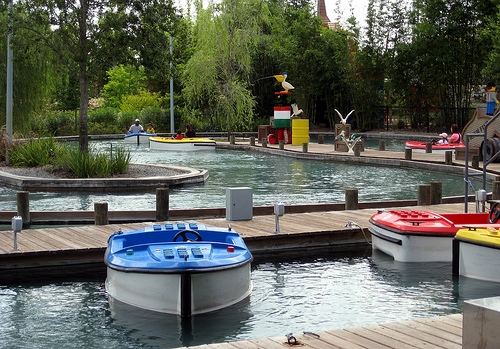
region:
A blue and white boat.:
[80, 186, 276, 326]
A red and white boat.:
[345, 190, 478, 268]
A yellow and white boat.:
[455, 205, 497, 291]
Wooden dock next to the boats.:
[155, 306, 478, 346]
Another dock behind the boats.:
[0, 185, 497, 268]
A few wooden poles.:
[11, 185, 181, 216]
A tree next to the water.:
[15, 1, 156, 171]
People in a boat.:
[115, 105, 160, 146]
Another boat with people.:
[391, 121, 471, 156]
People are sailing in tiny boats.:
[3, 5, 497, 347]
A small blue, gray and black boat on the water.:
[101, 221, 256, 318]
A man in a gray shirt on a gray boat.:
[125, 115, 145, 136]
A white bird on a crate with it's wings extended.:
[333, 106, 355, 124]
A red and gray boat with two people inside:
[400, 130, 465, 158]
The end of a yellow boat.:
[450, 220, 499, 285]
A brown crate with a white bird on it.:
[332, 121, 352, 150]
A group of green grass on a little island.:
[46, 144, 132, 176]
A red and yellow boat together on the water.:
[367, 205, 494, 285]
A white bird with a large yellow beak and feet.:
[271, 73, 296, 94]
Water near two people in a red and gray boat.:
[309, 129, 441, 146]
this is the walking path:
[48, 225, 95, 243]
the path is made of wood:
[41, 224, 92, 247]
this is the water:
[207, 152, 245, 177]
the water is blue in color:
[211, 155, 238, 173]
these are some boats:
[104, 212, 496, 319]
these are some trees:
[196, 2, 486, 65]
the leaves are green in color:
[186, 27, 241, 124]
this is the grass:
[58, 152, 118, 164]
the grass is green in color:
[56, 160, 91, 170]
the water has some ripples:
[280, 272, 337, 296]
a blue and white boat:
[96, 215, 269, 322]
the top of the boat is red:
[367, 211, 499, 231]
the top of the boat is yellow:
[454, 229, 499, 247]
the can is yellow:
[293, 114, 312, 144]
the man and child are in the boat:
[123, 117, 158, 136]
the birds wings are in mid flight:
[331, 107, 356, 124]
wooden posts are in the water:
[139, 184, 174, 217]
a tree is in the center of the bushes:
[74, 0, 91, 166]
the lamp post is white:
[163, 35, 179, 135]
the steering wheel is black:
[171, 227, 209, 246]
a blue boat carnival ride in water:
[92, 223, 299, 315]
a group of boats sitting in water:
[0, 91, 497, 344]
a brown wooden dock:
[173, 308, 468, 346]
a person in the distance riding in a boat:
[117, 113, 154, 155]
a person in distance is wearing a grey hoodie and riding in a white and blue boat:
[123, 114, 151, 147]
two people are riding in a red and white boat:
[404, 120, 465, 162]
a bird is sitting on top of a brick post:
[323, 97, 356, 152]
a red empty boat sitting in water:
[372, 201, 452, 281]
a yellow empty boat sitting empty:
[447, 215, 497, 285]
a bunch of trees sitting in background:
[0, 0, 498, 147]